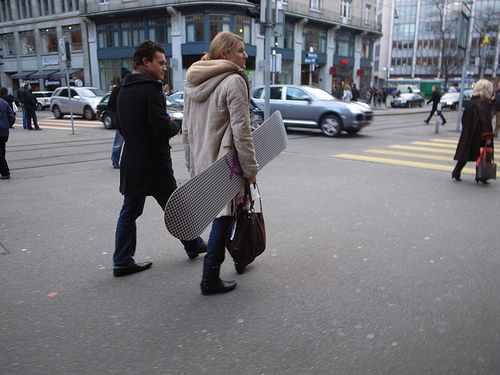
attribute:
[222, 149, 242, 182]
x — pink 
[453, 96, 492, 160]
coat — long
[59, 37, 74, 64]
pole — metal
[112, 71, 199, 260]
clothing — dark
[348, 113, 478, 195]
lines — yellow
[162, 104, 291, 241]
board — long 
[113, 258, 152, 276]
shoe — black, designer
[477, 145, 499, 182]
brown bag — brown 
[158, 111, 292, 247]
board — Black , white 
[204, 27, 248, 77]
hair — Blonde 